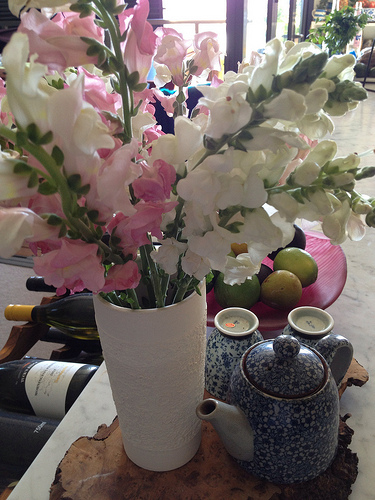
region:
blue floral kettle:
[202, 315, 352, 490]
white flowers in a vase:
[180, 88, 282, 313]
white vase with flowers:
[100, 273, 220, 490]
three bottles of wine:
[3, 261, 107, 450]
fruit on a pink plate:
[222, 233, 353, 312]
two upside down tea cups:
[211, 301, 339, 401]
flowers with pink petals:
[36, 146, 154, 289]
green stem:
[89, 3, 161, 164]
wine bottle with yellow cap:
[0, 296, 139, 359]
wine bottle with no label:
[0, 297, 115, 350]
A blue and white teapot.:
[196, 336, 356, 491]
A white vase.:
[80, 265, 224, 477]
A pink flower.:
[35, 235, 109, 303]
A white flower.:
[177, 146, 268, 203]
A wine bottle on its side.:
[6, 285, 96, 341]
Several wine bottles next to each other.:
[6, 270, 94, 412]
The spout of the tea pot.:
[182, 377, 258, 457]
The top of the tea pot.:
[244, 331, 328, 404]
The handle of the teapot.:
[312, 323, 362, 380]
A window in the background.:
[158, 0, 240, 38]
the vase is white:
[100, 303, 218, 466]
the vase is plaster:
[102, 300, 217, 473]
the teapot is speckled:
[211, 335, 351, 475]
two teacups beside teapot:
[218, 300, 325, 350]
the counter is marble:
[347, 186, 372, 359]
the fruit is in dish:
[228, 239, 337, 301]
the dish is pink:
[305, 233, 347, 302]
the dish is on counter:
[313, 230, 368, 322]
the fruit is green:
[216, 225, 323, 297]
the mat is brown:
[65, 430, 221, 499]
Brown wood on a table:
[67, 359, 355, 498]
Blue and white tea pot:
[211, 327, 369, 486]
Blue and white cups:
[202, 292, 372, 382]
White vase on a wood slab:
[73, 274, 233, 492]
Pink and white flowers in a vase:
[2, 28, 300, 302]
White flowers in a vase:
[148, 97, 353, 288]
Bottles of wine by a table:
[2, 278, 116, 453]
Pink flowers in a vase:
[12, 18, 179, 216]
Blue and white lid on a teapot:
[238, 328, 337, 403]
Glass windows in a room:
[159, 1, 323, 63]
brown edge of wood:
[75, 421, 117, 438]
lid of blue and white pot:
[193, 391, 224, 425]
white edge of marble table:
[23, 446, 61, 473]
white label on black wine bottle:
[10, 347, 86, 406]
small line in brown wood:
[84, 441, 110, 475]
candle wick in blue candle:
[284, 299, 347, 349]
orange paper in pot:
[213, 314, 262, 333]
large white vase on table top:
[74, 284, 251, 456]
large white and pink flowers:
[24, 21, 373, 286]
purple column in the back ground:
[197, 5, 283, 60]